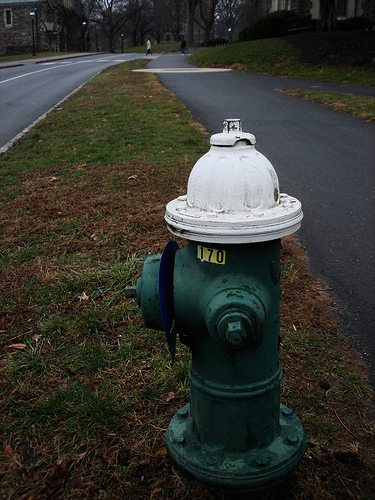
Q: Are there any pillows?
A: No, there are no pillows.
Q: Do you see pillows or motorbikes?
A: No, there are no pillows or motorbikes.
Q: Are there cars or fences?
A: No, there are no cars or fences.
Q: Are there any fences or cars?
A: No, there are no cars or fences.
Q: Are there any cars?
A: No, there are no cars.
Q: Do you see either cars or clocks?
A: No, there are no cars or clocks.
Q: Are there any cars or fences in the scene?
A: No, there are no cars or fences.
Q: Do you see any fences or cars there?
A: No, there are no cars or fences.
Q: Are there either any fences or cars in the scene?
A: No, there are no cars or fences.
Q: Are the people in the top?
A: Yes, the people are in the top of the image.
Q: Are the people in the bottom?
A: No, the people are in the top of the image.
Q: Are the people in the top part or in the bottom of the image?
A: The people are in the top of the image.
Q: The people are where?
A: The people are on the road.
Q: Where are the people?
A: The people are on the road.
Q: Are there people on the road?
A: Yes, there are people on the road.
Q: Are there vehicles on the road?
A: No, there are people on the road.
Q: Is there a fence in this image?
A: No, there are no fences.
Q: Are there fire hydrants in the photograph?
A: Yes, there is a fire hydrant.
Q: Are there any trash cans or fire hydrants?
A: Yes, there is a fire hydrant.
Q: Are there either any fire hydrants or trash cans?
A: Yes, there is a fire hydrant.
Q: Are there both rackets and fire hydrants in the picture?
A: No, there is a fire hydrant but no rackets.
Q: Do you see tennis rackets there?
A: No, there are no tennis rackets.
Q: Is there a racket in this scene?
A: No, there are no rackets.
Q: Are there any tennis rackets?
A: No, there are no tennis rackets.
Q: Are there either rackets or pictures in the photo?
A: No, there are no rackets or pictures.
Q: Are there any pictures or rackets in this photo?
A: No, there are no rackets or pictures.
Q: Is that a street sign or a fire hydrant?
A: That is a fire hydrant.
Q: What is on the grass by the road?
A: The fire hydrant is on the grass.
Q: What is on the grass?
A: The fire hydrant is on the grass.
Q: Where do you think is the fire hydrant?
A: The fire hydrant is on the grass.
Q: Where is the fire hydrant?
A: The fire hydrant is on the grass.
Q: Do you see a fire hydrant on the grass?
A: Yes, there is a fire hydrant on the grass.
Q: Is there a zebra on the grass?
A: No, there is a fire hydrant on the grass.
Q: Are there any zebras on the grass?
A: No, there is a fire hydrant on the grass.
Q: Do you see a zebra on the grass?
A: No, there is a fire hydrant on the grass.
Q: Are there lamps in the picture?
A: Yes, there is a lamp.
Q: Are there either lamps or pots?
A: Yes, there is a lamp.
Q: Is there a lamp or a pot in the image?
A: Yes, there is a lamp.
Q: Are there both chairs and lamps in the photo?
A: No, there is a lamp but no chairs.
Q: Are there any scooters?
A: No, there are no scooters.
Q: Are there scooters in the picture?
A: No, there are no scooters.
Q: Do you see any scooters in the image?
A: No, there are no scooters.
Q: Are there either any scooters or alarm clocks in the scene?
A: No, there are no scooters or alarm clocks.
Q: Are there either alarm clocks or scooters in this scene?
A: No, there are no scooters or alarm clocks.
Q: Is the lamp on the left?
A: Yes, the lamp is on the left of the image.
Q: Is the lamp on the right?
A: No, the lamp is on the left of the image.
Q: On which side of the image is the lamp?
A: The lamp is on the left of the image.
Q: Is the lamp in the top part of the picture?
A: Yes, the lamp is in the top of the image.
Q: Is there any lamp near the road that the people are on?
A: Yes, there is a lamp near the road.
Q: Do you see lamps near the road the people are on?
A: Yes, there is a lamp near the road.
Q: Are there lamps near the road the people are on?
A: Yes, there is a lamp near the road.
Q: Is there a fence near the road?
A: No, there is a lamp near the road.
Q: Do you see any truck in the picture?
A: No, there are no trucks.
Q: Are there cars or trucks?
A: No, there are no trucks or cars.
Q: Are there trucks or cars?
A: No, there are no trucks or cars.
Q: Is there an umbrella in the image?
A: No, there are no umbrellas.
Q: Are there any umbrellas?
A: No, there are no umbrellas.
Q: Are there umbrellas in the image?
A: No, there are no umbrellas.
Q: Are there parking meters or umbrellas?
A: No, there are no umbrellas or parking meters.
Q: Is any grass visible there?
A: Yes, there is grass.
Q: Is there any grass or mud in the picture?
A: Yes, there is grass.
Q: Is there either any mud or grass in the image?
A: Yes, there is grass.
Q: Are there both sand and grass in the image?
A: No, there is grass but no sand.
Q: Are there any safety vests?
A: No, there are no safety vests.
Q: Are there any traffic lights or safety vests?
A: No, there are no safety vests or traffic lights.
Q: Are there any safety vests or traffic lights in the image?
A: No, there are no safety vests or traffic lights.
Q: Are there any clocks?
A: No, there are no clocks.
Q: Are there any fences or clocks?
A: No, there are no clocks or fences.